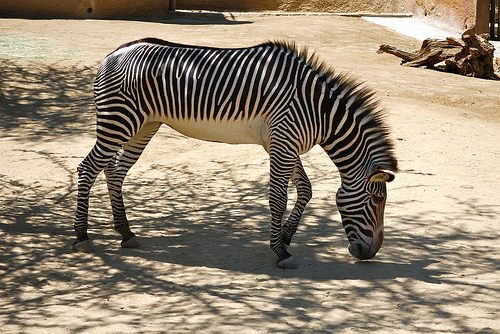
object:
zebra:
[74, 34, 399, 270]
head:
[333, 167, 396, 261]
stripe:
[262, 49, 284, 98]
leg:
[267, 133, 301, 257]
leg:
[74, 115, 140, 231]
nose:
[369, 241, 380, 259]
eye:
[371, 193, 387, 204]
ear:
[368, 168, 395, 184]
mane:
[264, 38, 398, 176]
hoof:
[121, 234, 141, 248]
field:
[0, 12, 499, 334]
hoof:
[276, 255, 300, 270]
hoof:
[279, 241, 289, 250]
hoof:
[72, 240, 93, 253]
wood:
[374, 25, 500, 81]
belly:
[159, 118, 262, 145]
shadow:
[0, 143, 499, 334]